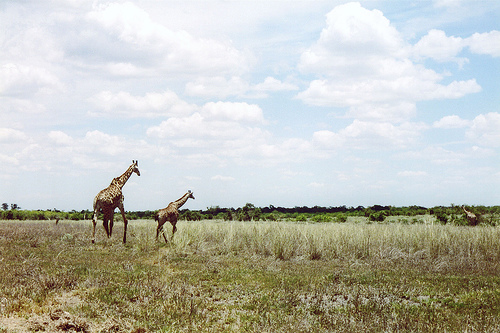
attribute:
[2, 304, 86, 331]
sandy soil — dried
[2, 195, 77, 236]
trees — taller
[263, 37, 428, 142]
sky — blue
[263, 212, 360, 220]
grass — greener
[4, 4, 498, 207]
sky — blue, white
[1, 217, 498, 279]
grasses — dried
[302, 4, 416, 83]
cloud — white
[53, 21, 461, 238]
sky — blue, white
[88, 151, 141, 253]
giraffe — taller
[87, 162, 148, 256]
giraffe — large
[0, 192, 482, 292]
plantation — grass